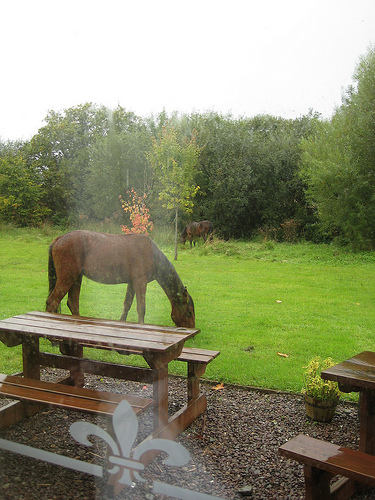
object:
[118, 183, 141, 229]
tree background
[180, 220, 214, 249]
horse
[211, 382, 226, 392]
leaf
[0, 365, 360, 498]
rocks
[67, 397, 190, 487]
decoration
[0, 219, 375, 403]
field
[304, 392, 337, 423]
planter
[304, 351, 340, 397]
flowers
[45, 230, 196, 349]
horse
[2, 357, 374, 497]
stone patch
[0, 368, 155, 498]
benches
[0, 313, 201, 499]
table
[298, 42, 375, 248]
tree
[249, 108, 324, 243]
tree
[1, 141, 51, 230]
tree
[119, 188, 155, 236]
tree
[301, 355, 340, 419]
potted plant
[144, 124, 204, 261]
tree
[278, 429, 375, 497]
bench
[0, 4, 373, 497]
window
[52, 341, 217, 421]
picnic bench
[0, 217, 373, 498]
backyard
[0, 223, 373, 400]
grass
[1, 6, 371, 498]
glass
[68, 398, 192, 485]
fleur